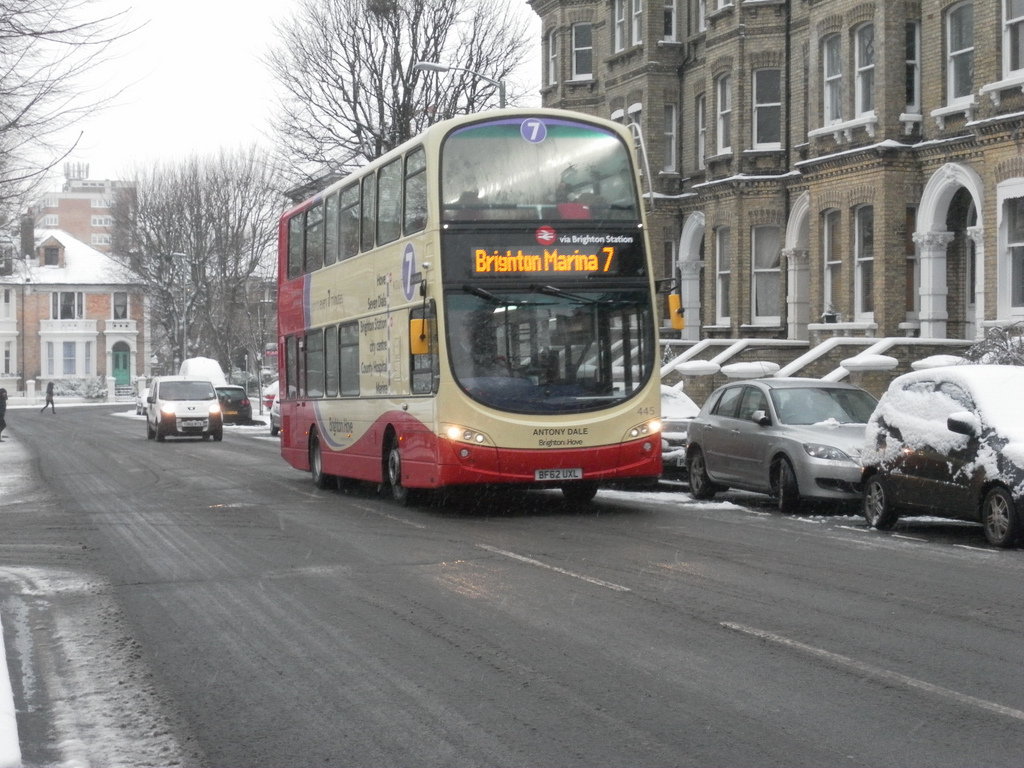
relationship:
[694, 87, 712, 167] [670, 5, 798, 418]
window adorning brownstone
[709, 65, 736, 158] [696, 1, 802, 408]
window adorning brownstone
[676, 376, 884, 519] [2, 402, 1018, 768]
car parked on road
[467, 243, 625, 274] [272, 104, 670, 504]
sign mounted on bus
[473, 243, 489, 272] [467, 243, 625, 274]
letter lit up on sign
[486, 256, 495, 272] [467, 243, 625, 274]
letter lit up on sign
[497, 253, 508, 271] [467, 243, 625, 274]
letter lit up on sign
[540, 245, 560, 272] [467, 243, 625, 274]
letter lit up on sign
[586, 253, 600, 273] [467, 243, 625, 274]
letter lit up on sign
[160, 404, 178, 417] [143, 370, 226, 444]
headlight mounted on car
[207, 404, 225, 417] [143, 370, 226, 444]
headlight mounted on car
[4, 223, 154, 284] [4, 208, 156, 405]
roof covering building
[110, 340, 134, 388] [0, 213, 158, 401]
door leading to building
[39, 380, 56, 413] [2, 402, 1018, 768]
person crossing road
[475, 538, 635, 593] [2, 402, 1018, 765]
line painted on road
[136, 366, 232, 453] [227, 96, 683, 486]
van behind bus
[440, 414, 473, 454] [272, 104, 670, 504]
headlight on bus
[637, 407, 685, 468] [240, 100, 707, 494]
light on bus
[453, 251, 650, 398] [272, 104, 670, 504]
windshield on bus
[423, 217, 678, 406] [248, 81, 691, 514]
windshield on bus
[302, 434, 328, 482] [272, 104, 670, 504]
wheel of bus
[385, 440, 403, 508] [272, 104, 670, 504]
wheel of bus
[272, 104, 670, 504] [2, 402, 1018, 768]
bus on road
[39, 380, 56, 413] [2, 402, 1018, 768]
person in road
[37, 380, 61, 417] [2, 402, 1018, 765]
person on road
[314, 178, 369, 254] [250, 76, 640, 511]
window of  the bus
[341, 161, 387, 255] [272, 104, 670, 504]
window of  the bus